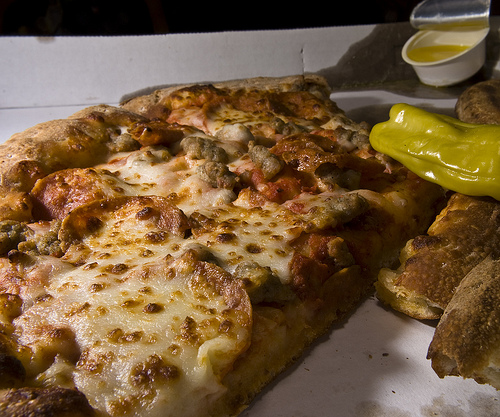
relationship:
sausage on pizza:
[23, 160, 196, 257] [21, 68, 417, 403]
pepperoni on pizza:
[29, 165, 126, 219] [21, 68, 417, 403]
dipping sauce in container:
[405, 42, 471, 62] [405, 23, 493, 90]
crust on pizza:
[0, 62, 321, 413] [21, 68, 417, 403]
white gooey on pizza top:
[105, 323, 170, 375] [0, 70, 359, 415]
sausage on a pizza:
[182, 137, 242, 187] [1, 68, 498, 415]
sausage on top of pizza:
[179, 136, 242, 187] [2, 70, 452, 412]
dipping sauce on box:
[405, 42, 471, 62] [330, 24, 499, 110]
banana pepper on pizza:
[368, 104, 499, 203] [1, 68, 498, 415]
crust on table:
[428, 252, 499, 387] [4, 1, 496, 415]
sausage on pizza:
[179, 136, 242, 187] [21, 68, 417, 403]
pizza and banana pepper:
[2, 70, 452, 412] [368, 104, 499, 203]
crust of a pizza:
[377, 193, 499, 387] [75, 112, 329, 335]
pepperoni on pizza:
[53, 193, 191, 243] [92, 99, 292, 410]